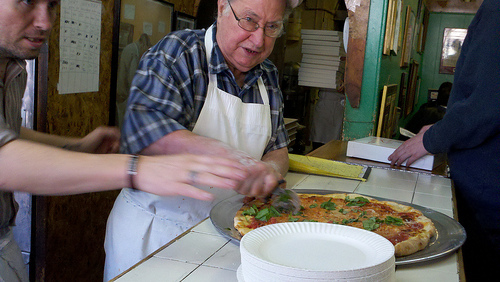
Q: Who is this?
A: Chef.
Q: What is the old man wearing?
A: Apron.